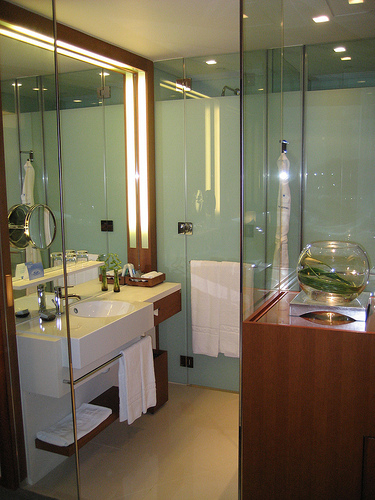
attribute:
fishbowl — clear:
[297, 243, 371, 303]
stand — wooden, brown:
[238, 291, 374, 497]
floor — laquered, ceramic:
[33, 386, 242, 497]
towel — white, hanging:
[188, 257, 252, 357]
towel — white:
[119, 335, 159, 422]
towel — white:
[35, 400, 115, 446]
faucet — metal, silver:
[51, 285, 79, 313]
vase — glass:
[112, 271, 122, 292]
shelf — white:
[13, 261, 104, 289]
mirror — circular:
[26, 205, 56, 250]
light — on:
[123, 66, 151, 248]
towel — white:
[269, 152, 291, 292]